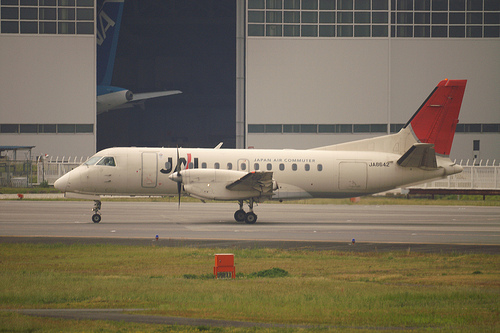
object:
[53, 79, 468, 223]
airplane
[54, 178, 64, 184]
nose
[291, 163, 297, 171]
window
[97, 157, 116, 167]
windows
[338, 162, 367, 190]
cargo door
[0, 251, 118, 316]
grass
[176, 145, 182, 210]
propeller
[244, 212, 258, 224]
wheel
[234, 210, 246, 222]
wheel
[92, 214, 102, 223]
wheel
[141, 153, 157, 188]
door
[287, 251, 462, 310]
grass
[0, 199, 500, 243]
runway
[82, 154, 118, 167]
cockpit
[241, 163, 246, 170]
window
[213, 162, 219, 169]
windows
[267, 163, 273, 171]
window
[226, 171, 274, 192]
wing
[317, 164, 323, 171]
windows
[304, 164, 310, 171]
windows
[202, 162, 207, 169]
windows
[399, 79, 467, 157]
tail fin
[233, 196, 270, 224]
landing gear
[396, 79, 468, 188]
tail